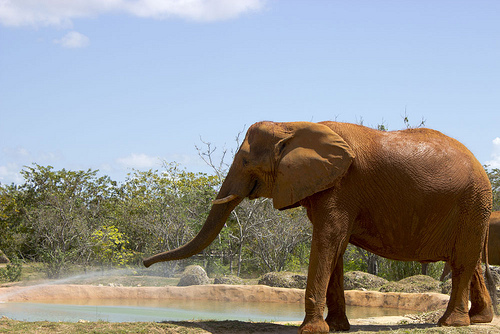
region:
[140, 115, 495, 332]
elephant walking across path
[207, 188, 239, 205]
white ivory tusk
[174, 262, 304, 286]
rocks on the edge of the pond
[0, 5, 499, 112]
clear blue sky with few white whispy clouds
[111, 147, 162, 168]
whispy white clouds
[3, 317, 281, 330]
patch of dry grass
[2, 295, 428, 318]
small body of water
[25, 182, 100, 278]
small safari bush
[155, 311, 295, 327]
shadow of the elephant on the path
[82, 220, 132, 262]
small bush with lime-green foliage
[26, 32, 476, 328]
this is a nature setting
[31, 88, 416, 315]
the elephant is spraying water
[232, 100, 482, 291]
the elephant is orange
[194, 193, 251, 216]
the elephant has tusks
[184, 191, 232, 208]
the tusks are ivory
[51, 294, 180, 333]
this is a creek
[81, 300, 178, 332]
the water here is blue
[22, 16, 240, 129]
the weather is partly cloudy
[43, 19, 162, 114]
the sky is blue and white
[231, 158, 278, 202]
the elephant is smirking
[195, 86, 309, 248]
head of an elephant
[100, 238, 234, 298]
nose of an elephant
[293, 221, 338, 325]
leg of an elephant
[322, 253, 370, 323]
leg of an elephant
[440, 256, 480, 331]
leg of an elephant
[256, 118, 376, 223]
ear of an elephant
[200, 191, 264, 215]
trunk of an elephant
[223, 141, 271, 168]
eye of an elephant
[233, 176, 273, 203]
mouth of an elephant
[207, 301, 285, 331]
shadow of an elephant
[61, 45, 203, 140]
blue sky above the land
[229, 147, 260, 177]
eye of the elephant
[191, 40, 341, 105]
blue sky in the photo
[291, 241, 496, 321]
legs of the elephant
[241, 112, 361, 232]
ear of the elephant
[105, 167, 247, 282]
trunk of the elephant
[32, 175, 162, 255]
branches of the trees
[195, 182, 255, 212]
white tusk of the elephant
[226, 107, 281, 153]
top of the elephant's head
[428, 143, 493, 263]
back of the elephant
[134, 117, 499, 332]
an elephant next to a watering hole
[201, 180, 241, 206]
tusk of an elephant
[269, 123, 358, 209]
floppy large elephant ear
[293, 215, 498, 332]
four elephant legs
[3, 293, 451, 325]
pool of water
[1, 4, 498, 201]
a few white clouds in a blue sky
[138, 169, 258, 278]
trunk of an elephant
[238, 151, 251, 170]
eye of an elephant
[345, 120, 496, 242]
wrinkled skin on an elephants back